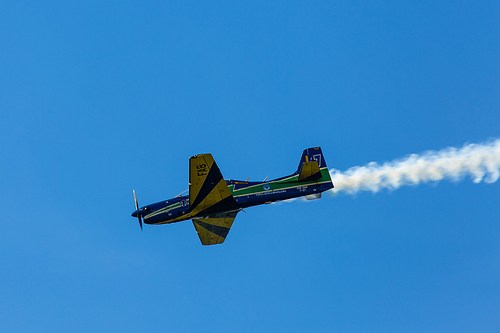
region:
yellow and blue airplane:
[111, 128, 473, 266]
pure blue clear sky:
[45, 33, 227, 110]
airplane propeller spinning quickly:
[124, 186, 153, 233]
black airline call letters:
[189, 147, 216, 188]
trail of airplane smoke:
[335, 166, 487, 194]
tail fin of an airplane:
[286, 142, 345, 203]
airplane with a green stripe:
[113, 129, 360, 256]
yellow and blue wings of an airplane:
[180, 148, 256, 261]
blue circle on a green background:
[259, 176, 280, 199]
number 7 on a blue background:
[303, 146, 330, 176]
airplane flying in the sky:
[122, 140, 364, 261]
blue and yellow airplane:
[124, 128, 346, 265]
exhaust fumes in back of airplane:
[304, 117, 485, 256]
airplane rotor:
[114, 167, 164, 252]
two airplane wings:
[179, 147, 239, 284]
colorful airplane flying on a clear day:
[34, 26, 472, 314]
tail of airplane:
[275, 126, 368, 248]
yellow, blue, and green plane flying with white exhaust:
[18, 43, 469, 320]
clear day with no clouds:
[29, 31, 471, 316]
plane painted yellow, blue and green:
[100, 125, 382, 261]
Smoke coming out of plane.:
[361, 161, 493, 233]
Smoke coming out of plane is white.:
[336, 155, 473, 207]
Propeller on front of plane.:
[124, 183, 159, 255]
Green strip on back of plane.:
[205, 177, 367, 208]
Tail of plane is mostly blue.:
[288, 143, 376, 233]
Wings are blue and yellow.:
[187, 153, 232, 317]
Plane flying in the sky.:
[104, 133, 337, 288]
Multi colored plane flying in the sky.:
[105, 125, 434, 252]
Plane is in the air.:
[106, 158, 352, 285]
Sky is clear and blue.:
[100, 225, 459, 310]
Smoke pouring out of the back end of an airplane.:
[290, 139, 498, 204]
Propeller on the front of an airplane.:
[127, 187, 142, 230]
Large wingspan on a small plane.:
[177, 143, 243, 284]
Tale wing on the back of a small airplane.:
[292, 141, 338, 204]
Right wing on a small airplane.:
[186, 209, 243, 260]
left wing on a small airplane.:
[184, 139, 232, 203]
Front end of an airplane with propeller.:
[114, 191, 189, 244]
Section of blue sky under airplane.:
[250, 234, 437, 317]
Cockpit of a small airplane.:
[184, 171, 255, 199]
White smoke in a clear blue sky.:
[390, 142, 429, 182]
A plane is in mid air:
[103, 119, 370, 289]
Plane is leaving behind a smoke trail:
[288, 134, 499, 211]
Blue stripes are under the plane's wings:
[168, 145, 243, 266]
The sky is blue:
[26, 17, 471, 272]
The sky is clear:
[15, 0, 480, 330]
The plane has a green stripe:
[227, 128, 349, 243]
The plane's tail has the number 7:
[303, 142, 338, 173]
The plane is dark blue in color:
[90, 125, 350, 260]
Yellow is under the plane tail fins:
[286, 147, 336, 207]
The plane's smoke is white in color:
[271, 121, 497, 224]